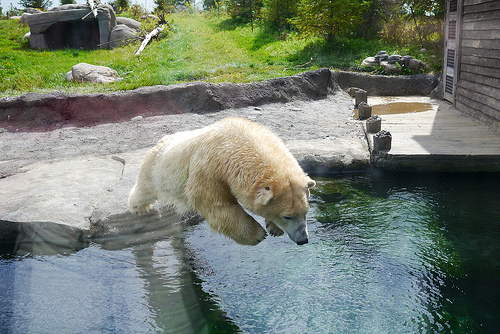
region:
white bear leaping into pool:
[113, 108, 358, 288]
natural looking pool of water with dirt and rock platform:
[31, 86, 423, 311]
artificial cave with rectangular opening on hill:
[7, 2, 157, 57]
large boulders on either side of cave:
[17, 5, 157, 50]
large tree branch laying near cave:
[135, 1, 180, 61]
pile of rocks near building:
[355, 40, 461, 95]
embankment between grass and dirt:
[30, 50, 365, 110]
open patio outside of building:
[345, 0, 490, 170]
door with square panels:
[437, 0, 457, 117]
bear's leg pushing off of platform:
[120, 142, 181, 237]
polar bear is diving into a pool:
[116, 121, 336, 274]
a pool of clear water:
[11, 175, 494, 331]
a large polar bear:
[122, 120, 354, 257]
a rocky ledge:
[1, 100, 376, 197]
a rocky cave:
[15, 7, 150, 61]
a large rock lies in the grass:
[59, 60, 133, 92]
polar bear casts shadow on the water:
[126, 233, 228, 329]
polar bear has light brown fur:
[182, 134, 304, 236]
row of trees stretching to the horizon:
[220, 0, 355, 50]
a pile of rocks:
[359, 44, 435, 81]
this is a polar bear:
[138, 116, 323, 241]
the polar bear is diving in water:
[124, 115, 321, 240]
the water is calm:
[1, 254, 499, 332]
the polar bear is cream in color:
[121, 113, 316, 238]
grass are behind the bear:
[174, 0, 263, 71]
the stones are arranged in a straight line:
[350, 87, 391, 149]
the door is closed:
[441, 18, 459, 95]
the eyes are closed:
[280, 209, 311, 222]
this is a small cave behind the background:
[9, 0, 136, 54]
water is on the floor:
[381, 98, 425, 113]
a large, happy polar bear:
[115, 117, 329, 265]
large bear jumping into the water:
[123, 116, 368, 286]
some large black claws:
[239, 220, 286, 253]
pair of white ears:
[247, 177, 322, 207]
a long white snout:
[283, 216, 312, 253]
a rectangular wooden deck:
[331, 61, 498, 168]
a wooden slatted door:
[435, 2, 467, 104]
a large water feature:
[39, 127, 489, 332]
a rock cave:
[1, 0, 163, 84]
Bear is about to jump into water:
[112, 106, 348, 266]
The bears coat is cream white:
[121, 90, 360, 290]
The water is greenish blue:
[264, 182, 498, 329]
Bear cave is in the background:
[27, 2, 129, 57]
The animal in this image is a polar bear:
[133, 114, 336, 265]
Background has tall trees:
[201, 0, 426, 53]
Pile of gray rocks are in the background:
[358, 41, 428, 81]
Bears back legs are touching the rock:
[56, 141, 236, 246]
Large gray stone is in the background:
[63, 56, 134, 97]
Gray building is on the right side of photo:
[432, 3, 499, 128]